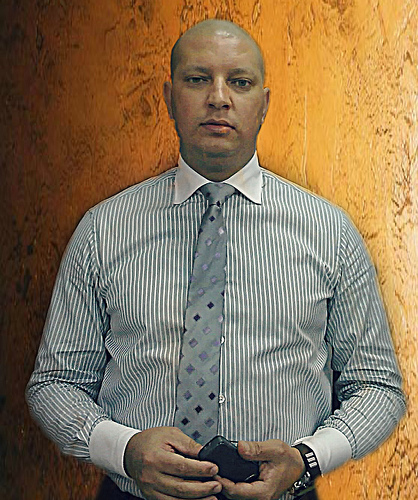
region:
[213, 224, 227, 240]
Small purple diamond on a mans tie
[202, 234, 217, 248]
Small purple diamond on a mans tie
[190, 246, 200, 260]
Small purple diamond on a mans tie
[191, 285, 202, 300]
Small purple diamond on a mans tie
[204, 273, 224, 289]
Small purple diamond on a mans tie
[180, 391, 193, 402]
Small purple diamond on a mans tie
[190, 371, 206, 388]
Small purple diamond on a mans tie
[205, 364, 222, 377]
Small purple diamond on a mans tie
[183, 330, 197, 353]
Small purple diamond on a mans tie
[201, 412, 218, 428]
Small purple diamond on a mans tie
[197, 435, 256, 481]
A cell phone in the man's hands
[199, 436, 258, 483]
The cell phone is black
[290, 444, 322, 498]
A watch on the man's hands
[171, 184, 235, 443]
The man is wearing a tie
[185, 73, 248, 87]
The eyes of the man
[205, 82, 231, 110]
The nose of the man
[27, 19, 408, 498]
A man holding a cell phone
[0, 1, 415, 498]
A wall behind the man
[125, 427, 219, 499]
The right hand of the man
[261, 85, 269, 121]
The left ear of the man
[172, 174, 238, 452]
the tie is gray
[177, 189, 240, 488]
the tie is gray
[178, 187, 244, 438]
the tie is gray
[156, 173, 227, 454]
the tie is gray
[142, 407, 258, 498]
a phone in man's hands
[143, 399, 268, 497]
a phone in man's hands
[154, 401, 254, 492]
a phone in man's hands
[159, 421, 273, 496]
a phone in man's hands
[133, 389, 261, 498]
a phone in man's hands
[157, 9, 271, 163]
The head of the person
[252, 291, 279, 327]
Part of the shirt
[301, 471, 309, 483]
Part of the watch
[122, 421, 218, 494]
The right hand of the person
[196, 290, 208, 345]
Part of the tie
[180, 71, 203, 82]
The right eye of the person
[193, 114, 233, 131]
The mouth of the person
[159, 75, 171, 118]
The right ear of the person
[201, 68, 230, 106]
The nose of the person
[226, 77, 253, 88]
The left eye of the person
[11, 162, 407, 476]
man wearing a striped shirt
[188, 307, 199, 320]
square on the grey tie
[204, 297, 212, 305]
square on the grey tie